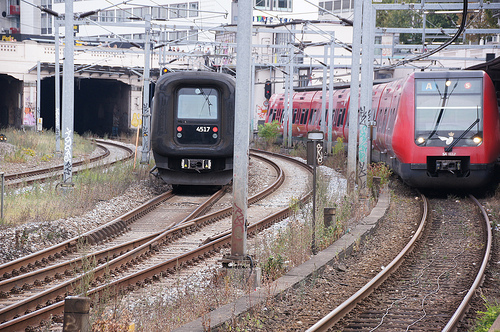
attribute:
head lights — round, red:
[154, 124, 240, 149]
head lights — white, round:
[414, 131, 477, 148]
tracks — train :
[10, 199, 499, 329]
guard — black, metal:
[407, 144, 482, 181]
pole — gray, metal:
[229, 0, 259, 261]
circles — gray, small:
[175, 130, 220, 145]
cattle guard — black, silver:
[434, 156, 461, 176]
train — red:
[377, 74, 487, 195]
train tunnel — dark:
[39, 72, 135, 140]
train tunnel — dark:
[0, 71, 39, 128]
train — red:
[263, 64, 498, 198]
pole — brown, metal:
[306, 129, 327, 255]